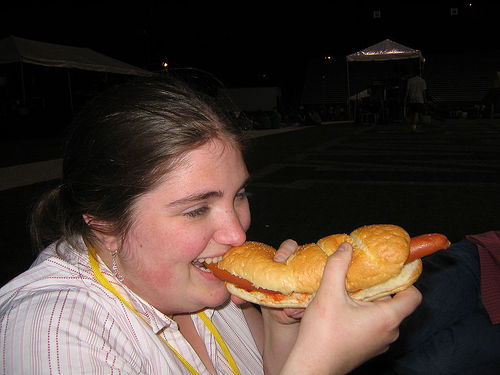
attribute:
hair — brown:
[19, 77, 241, 259]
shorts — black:
[400, 95, 430, 116]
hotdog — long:
[211, 222, 449, 311]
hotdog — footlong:
[203, 229, 456, 313]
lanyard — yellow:
[76, 227, 238, 372]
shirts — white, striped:
[1, 215, 262, 372]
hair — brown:
[32, 80, 232, 235]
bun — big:
[227, 219, 418, 296]